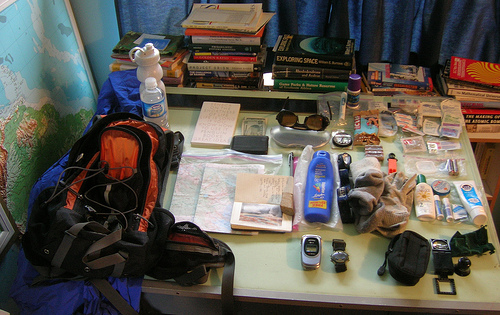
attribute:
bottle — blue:
[302, 149, 333, 222]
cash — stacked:
[241, 114, 265, 144]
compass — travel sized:
[430, 238, 455, 294]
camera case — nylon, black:
[377, 229, 431, 286]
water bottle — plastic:
[140, 73, 169, 127]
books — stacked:
[183, 3, 273, 90]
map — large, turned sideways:
[1, 1, 96, 234]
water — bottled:
[139, 80, 180, 130]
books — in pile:
[105, 4, 355, 96]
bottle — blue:
[298, 149, 339, 222]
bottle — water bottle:
[139, 74, 172, 136]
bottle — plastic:
[403, 164, 439, 222]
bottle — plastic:
[133, 73, 172, 131]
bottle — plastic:
[297, 143, 343, 226]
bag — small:
[373, 226, 433, 282]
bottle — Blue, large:
[301, 139, 343, 223]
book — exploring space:
[267, 29, 362, 70]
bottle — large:
[124, 37, 181, 136]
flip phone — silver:
[295, 226, 324, 275]